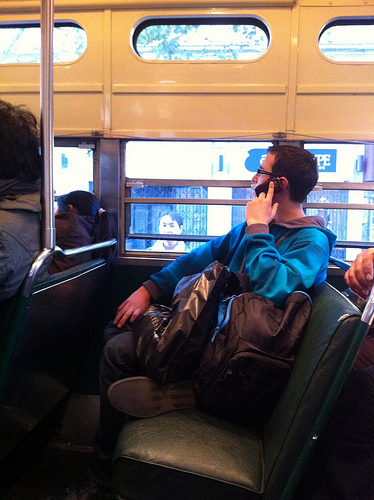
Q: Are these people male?
A: No, they are both male and female.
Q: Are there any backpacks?
A: Yes, there is a backpack.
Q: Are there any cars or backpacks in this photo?
A: Yes, there is a backpack.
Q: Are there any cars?
A: No, there are no cars.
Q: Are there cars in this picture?
A: No, there are no cars.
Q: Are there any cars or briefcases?
A: No, there are no cars or briefcases.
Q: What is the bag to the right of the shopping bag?
A: The bag is a backpack.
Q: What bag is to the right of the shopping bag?
A: The bag is a backpack.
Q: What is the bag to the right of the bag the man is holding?
A: The bag is a backpack.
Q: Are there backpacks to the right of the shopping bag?
A: Yes, there is a backpack to the right of the shopping bag.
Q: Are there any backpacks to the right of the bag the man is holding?
A: Yes, there is a backpack to the right of the shopping bag.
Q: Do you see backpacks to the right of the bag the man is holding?
A: Yes, there is a backpack to the right of the shopping bag.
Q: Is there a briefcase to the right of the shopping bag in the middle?
A: No, there is a backpack to the right of the shopping bag.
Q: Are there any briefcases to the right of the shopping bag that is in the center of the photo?
A: No, there is a backpack to the right of the shopping bag.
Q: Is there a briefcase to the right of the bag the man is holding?
A: No, there is a backpack to the right of the shopping bag.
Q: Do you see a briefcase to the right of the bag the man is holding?
A: No, there is a backpack to the right of the shopping bag.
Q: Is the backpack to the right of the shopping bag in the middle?
A: Yes, the backpack is to the right of the shopping bag.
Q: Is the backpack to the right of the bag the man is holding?
A: Yes, the backpack is to the right of the shopping bag.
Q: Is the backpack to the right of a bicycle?
A: No, the backpack is to the right of the shopping bag.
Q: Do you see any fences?
A: No, there are no fences.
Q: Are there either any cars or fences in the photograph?
A: No, there are no fences or cars.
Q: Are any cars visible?
A: No, there are no cars.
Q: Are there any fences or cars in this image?
A: No, there are no cars or fences.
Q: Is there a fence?
A: No, there are no fences.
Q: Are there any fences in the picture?
A: No, there are no fences.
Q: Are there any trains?
A: Yes, there is a train.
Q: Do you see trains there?
A: Yes, there is a train.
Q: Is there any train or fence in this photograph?
A: Yes, there is a train.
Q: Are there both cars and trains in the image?
A: No, there is a train but no cars.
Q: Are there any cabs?
A: No, there are no cabs.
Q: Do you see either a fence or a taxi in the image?
A: No, there are no taxis or fences.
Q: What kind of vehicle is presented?
A: The vehicle is a train.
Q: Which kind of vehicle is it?
A: The vehicle is a train.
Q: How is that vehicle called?
A: This is a train.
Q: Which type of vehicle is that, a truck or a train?
A: This is a train.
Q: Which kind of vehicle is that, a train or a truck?
A: This is a train.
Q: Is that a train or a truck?
A: That is a train.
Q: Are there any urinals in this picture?
A: No, there are no urinals.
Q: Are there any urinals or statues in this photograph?
A: No, there are no urinals or statues.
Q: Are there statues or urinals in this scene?
A: No, there are no urinals or statues.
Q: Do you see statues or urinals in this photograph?
A: No, there are no urinals or statues.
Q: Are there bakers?
A: No, there are no bakers.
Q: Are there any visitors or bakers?
A: No, there are no bakers or visitors.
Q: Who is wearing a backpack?
A: The man is wearing a backpack.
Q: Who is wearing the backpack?
A: The man is wearing a backpack.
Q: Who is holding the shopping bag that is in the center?
A: The man is holding the shopping bag.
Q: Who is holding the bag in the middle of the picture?
A: The man is holding the shopping bag.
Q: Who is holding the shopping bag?
A: The man is holding the shopping bag.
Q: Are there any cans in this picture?
A: No, there are no cans.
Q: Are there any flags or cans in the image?
A: No, there are no cans or flags.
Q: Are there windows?
A: Yes, there is a window.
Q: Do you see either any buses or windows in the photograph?
A: Yes, there is a window.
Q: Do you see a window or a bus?
A: Yes, there is a window.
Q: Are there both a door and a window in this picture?
A: No, there is a window but no doors.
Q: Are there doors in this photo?
A: No, there are no doors.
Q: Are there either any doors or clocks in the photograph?
A: No, there are no doors or clocks.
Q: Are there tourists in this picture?
A: No, there are no tourists.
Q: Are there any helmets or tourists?
A: No, there are no tourists or helmets.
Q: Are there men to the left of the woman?
A: Yes, there is a man to the left of the woman.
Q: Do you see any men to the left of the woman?
A: Yes, there is a man to the left of the woman.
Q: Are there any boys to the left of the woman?
A: No, there is a man to the left of the woman.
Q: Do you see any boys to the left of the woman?
A: No, there is a man to the left of the woman.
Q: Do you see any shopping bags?
A: Yes, there is a shopping bag.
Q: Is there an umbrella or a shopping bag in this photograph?
A: Yes, there is a shopping bag.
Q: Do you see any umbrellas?
A: No, there are no umbrellas.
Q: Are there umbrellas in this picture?
A: No, there are no umbrellas.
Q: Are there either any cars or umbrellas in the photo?
A: No, there are no umbrellas or cars.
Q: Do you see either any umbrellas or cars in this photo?
A: No, there are no umbrellas or cars.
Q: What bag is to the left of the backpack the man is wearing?
A: The bag is a shopping bag.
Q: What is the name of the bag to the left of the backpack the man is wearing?
A: The bag is a shopping bag.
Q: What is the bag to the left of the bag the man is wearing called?
A: The bag is a shopping bag.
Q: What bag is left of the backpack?
A: The bag is a shopping bag.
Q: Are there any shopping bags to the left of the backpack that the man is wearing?
A: Yes, there is a shopping bag to the left of the backpack.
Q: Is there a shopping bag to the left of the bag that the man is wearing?
A: Yes, there is a shopping bag to the left of the backpack.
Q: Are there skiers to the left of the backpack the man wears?
A: No, there is a shopping bag to the left of the backpack.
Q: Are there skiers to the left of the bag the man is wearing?
A: No, there is a shopping bag to the left of the backpack.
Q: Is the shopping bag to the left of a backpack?
A: Yes, the shopping bag is to the left of a backpack.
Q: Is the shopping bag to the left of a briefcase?
A: No, the shopping bag is to the left of a backpack.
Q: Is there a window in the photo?
A: Yes, there is a window.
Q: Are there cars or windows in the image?
A: Yes, there is a window.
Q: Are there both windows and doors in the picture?
A: No, there is a window but no doors.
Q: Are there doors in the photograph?
A: No, there are no doors.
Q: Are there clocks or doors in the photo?
A: No, there are no doors or clocks.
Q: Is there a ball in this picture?
A: No, there are no balls.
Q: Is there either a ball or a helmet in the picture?
A: No, there are no balls or helmets.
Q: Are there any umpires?
A: No, there are no umpires.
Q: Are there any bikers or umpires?
A: No, there are no umpires or bikers.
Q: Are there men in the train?
A: Yes, there is a man in the train.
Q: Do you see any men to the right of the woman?
A: Yes, there is a man to the right of the woman.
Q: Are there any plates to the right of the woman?
A: No, there is a man to the right of the woman.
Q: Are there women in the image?
A: Yes, there is a woman.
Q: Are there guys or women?
A: Yes, there is a woman.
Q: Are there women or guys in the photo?
A: Yes, there is a woman.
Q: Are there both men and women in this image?
A: Yes, there are both a woman and a man.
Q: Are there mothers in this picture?
A: No, there are no mothers.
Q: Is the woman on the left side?
A: Yes, the woman is on the left of the image.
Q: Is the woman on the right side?
A: No, the woman is on the left of the image.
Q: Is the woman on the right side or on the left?
A: The woman is on the left of the image.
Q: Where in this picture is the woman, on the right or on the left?
A: The woman is on the left of the image.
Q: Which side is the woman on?
A: The woman is on the left of the image.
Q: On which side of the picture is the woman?
A: The woman is on the left of the image.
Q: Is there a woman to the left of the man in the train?
A: Yes, there is a woman to the left of the man.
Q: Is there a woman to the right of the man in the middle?
A: No, the woman is to the left of the man.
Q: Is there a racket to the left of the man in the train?
A: No, there is a woman to the left of the man.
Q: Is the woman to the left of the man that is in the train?
A: Yes, the woman is to the left of the man.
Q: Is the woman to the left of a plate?
A: No, the woman is to the left of the man.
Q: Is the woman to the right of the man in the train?
A: No, the woman is to the left of the man.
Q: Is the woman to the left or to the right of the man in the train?
A: The woman is to the left of the man.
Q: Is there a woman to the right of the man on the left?
A: Yes, there is a woman to the right of the man.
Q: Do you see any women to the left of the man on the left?
A: No, the woman is to the right of the man.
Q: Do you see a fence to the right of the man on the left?
A: No, there is a woman to the right of the man.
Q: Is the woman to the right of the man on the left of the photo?
A: Yes, the woman is to the right of the man.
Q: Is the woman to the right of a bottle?
A: No, the woman is to the right of the man.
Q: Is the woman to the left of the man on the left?
A: No, the woman is to the right of the man.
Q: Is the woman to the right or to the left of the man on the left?
A: The woman is to the right of the man.